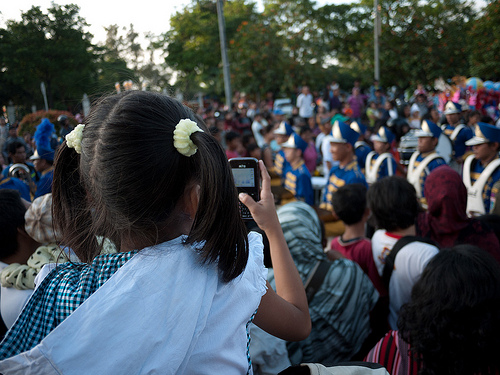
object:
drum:
[311, 207, 333, 222]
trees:
[146, 2, 272, 92]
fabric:
[0, 227, 266, 375]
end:
[242, 306, 258, 373]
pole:
[372, 1, 381, 91]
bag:
[362, 235, 434, 354]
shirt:
[0, 265, 38, 328]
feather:
[33, 117, 54, 161]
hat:
[29, 146, 55, 161]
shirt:
[0, 230, 272, 375]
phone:
[224, 157, 264, 222]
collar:
[335, 235, 366, 246]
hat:
[323, 120, 363, 146]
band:
[269, 111, 498, 215]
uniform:
[462, 124, 497, 219]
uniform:
[407, 120, 447, 210]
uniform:
[318, 120, 366, 212]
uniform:
[29, 146, 59, 198]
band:
[1, 119, 59, 204]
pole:
[216, 0, 232, 109]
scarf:
[274, 202, 379, 367]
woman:
[265, 201, 381, 364]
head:
[275, 201, 321, 264]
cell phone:
[227, 157, 262, 230]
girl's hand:
[237, 159, 279, 230]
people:
[367, 175, 438, 330]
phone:
[223, 152, 261, 224]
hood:
[1, 234, 207, 373]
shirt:
[331, 234, 384, 292]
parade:
[2, 119, 499, 219]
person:
[329, 182, 380, 296]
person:
[416, 166, 499, 252]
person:
[348, 82, 365, 115]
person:
[411, 92, 431, 116]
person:
[296, 85, 315, 124]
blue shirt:
[320, 162, 368, 218]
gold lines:
[329, 175, 345, 188]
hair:
[51, 88, 249, 284]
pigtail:
[49, 131, 106, 262]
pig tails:
[180, 128, 248, 284]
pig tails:
[55, 135, 95, 263]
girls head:
[74, 88, 202, 242]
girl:
[0, 88, 313, 373]